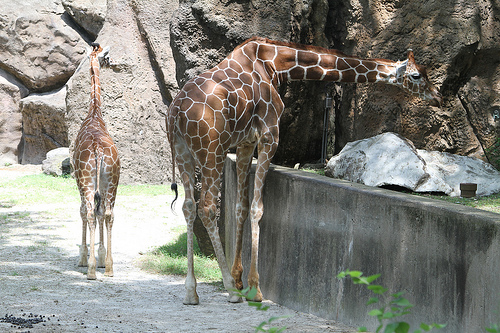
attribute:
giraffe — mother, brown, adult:
[165, 36, 444, 305]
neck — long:
[260, 36, 399, 89]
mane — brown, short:
[254, 34, 392, 64]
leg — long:
[248, 132, 278, 307]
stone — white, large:
[325, 133, 498, 198]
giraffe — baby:
[73, 43, 119, 280]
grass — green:
[157, 229, 220, 282]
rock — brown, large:
[63, 1, 109, 37]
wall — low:
[225, 150, 499, 330]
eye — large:
[413, 74, 420, 81]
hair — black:
[171, 185, 178, 209]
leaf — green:
[353, 269, 361, 280]